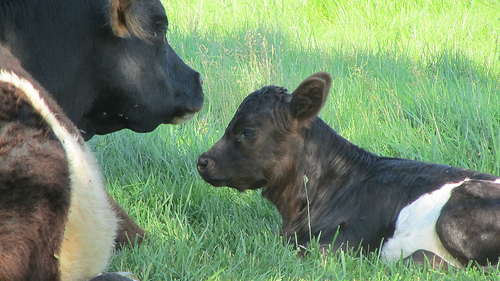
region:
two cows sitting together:
[50, 10, 428, 194]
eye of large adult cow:
[124, 15, 174, 66]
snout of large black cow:
[112, 58, 217, 125]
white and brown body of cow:
[1, 125, 112, 197]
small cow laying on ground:
[81, 55, 472, 263]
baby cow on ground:
[177, 31, 432, 279]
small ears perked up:
[258, 61, 346, 145]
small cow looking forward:
[170, 60, 358, 198]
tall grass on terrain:
[28, 150, 236, 278]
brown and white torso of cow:
[235, 111, 476, 279]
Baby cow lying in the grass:
[197, 70, 478, 280]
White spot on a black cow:
[382, 163, 467, 272]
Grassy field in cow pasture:
[224, 1, 481, 76]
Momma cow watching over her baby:
[10, 7, 212, 135]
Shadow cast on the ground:
[216, 16, 486, 105]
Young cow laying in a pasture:
[195, 65, 482, 275]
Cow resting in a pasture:
[196, 68, 493, 276]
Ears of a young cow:
[289, 67, 335, 128]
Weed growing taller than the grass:
[295, 172, 332, 254]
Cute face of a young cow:
[193, 60, 336, 214]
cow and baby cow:
[14, 6, 387, 222]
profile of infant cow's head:
[188, 44, 343, 216]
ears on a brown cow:
[277, 51, 349, 131]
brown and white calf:
[199, 48, 499, 267]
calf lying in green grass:
[200, 35, 486, 280]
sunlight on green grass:
[256, 10, 489, 79]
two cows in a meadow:
[48, 4, 459, 254]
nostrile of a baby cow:
[192, 142, 223, 190]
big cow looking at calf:
[75, 2, 415, 237]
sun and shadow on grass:
[337, 12, 484, 125]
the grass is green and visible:
[336, 51, 463, 123]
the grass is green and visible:
[351, 28, 464, 198]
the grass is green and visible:
[366, 63, 443, 167]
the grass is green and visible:
[420, 76, 483, 113]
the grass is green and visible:
[385, 76, 492, 121]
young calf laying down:
[185, 72, 499, 259]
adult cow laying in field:
[6, 2, 210, 274]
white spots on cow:
[354, 161, 474, 266]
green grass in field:
[213, 2, 499, 64]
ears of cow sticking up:
[291, 72, 346, 129]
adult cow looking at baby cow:
[4, 2, 370, 203]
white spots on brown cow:
[1, 68, 115, 276]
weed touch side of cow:
[286, 169, 328, 255]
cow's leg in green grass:
[86, 190, 168, 257]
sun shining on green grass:
[188, 2, 499, 72]